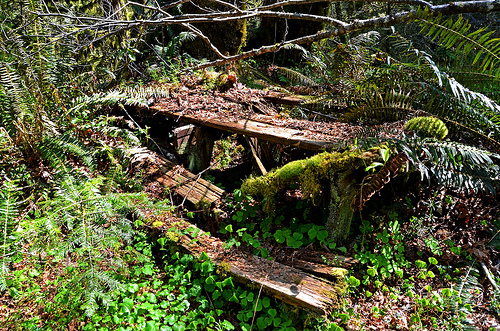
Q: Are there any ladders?
A: No, there are no ladders.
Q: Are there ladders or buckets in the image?
A: No, there are no ladders or buckets.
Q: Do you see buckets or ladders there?
A: No, there are no ladders or buckets.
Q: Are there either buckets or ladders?
A: No, there are no ladders or buckets.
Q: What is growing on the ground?
A: The vine is growing on the ground.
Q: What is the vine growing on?
A: The vine is growing on the ground.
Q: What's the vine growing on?
A: The vine is growing on the ground.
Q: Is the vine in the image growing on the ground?
A: Yes, the vine is growing on the ground.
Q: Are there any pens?
A: No, there are no pens.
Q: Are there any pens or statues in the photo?
A: No, there are no pens or statues.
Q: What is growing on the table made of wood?
A: The moss is growing on the table.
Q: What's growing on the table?
A: The moss is growing on the table.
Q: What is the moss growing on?
A: The moss is growing on the table.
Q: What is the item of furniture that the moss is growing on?
A: The piece of furniture is a table.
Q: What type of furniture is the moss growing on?
A: The moss is growing on the table.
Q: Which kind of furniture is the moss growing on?
A: The moss is growing on the table.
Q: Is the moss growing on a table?
A: Yes, the moss is growing on a table.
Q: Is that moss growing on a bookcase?
A: No, the moss is growing on a table.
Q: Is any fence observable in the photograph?
A: No, there are no fences.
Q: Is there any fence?
A: No, there are no fences.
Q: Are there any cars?
A: No, there are no cars.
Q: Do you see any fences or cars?
A: No, there are no cars or fences.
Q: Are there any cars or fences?
A: No, there are no cars or fences.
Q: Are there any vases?
A: No, there are no vases.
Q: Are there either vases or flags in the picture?
A: No, there are no vases or flags.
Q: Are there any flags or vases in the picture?
A: No, there are no vases or flags.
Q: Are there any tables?
A: Yes, there is a table.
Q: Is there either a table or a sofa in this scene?
A: Yes, there is a table.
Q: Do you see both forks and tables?
A: No, there is a table but no forks.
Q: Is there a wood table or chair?
A: Yes, there is a wood table.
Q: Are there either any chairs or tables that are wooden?
A: Yes, the table is wooden.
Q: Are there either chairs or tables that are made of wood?
A: Yes, the table is made of wood.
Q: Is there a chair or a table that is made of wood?
A: Yes, the table is made of wood.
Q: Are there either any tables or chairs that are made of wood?
A: Yes, the table is made of wood.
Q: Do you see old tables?
A: Yes, there is an old table.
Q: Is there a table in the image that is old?
A: Yes, there is a table that is old.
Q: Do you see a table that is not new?
A: Yes, there is a old table.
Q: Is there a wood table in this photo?
A: Yes, there is a wood table.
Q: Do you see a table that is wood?
A: Yes, there is a wood table.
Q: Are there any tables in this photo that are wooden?
A: Yes, there is a table that is wooden.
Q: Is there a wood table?
A: Yes, there is a table that is made of wood.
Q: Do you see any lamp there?
A: No, there are no lamps.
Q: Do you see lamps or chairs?
A: No, there are no lamps or chairs.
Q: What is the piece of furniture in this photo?
A: The piece of furniture is a table.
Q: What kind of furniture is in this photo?
A: The furniture is a table.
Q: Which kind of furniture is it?
A: The piece of furniture is a table.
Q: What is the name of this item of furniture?
A: This is a table.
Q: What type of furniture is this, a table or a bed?
A: This is a table.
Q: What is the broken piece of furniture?
A: The piece of furniture is a table.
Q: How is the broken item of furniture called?
A: The piece of furniture is a table.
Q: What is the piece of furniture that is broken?
A: The piece of furniture is a table.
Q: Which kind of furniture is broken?
A: The furniture is a table.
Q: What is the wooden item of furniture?
A: The piece of furniture is a table.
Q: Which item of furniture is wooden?
A: The piece of furniture is a table.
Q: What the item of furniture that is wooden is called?
A: The piece of furniture is a table.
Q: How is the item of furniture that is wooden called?
A: The piece of furniture is a table.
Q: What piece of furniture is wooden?
A: The piece of furniture is a table.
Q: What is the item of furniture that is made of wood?
A: The piece of furniture is a table.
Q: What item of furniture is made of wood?
A: The piece of furniture is a table.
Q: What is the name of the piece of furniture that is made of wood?
A: The piece of furniture is a table.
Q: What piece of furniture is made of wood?
A: The piece of furniture is a table.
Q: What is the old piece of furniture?
A: The piece of furniture is a table.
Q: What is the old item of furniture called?
A: The piece of furniture is a table.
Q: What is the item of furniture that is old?
A: The piece of furniture is a table.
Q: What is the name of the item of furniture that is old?
A: The piece of furniture is a table.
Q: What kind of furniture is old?
A: The furniture is a table.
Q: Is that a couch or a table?
A: That is a table.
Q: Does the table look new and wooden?
A: No, the table is wooden but old.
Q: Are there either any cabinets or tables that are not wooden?
A: No, there is a table but it is wooden.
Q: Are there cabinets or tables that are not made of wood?
A: No, there is a table but it is made of wood.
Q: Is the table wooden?
A: Yes, the table is wooden.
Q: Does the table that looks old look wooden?
A: Yes, the table is wooden.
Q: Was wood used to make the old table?
A: Yes, the table is made of wood.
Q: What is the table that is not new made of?
A: The table is made of wood.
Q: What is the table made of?
A: The table is made of wood.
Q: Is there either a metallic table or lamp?
A: No, there is a table but it is wooden.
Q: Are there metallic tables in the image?
A: No, there is a table but it is wooden.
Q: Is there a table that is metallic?
A: No, there is a table but it is wooden.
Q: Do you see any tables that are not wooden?
A: No, there is a table but it is wooden.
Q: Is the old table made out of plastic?
A: No, the table is made of wood.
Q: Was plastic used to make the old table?
A: No, the table is made of wood.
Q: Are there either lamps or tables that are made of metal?
A: No, there is a table but it is made of wood.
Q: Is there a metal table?
A: No, there is a table but it is made of wood.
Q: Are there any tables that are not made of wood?
A: No, there is a table but it is made of wood.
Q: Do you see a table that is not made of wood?
A: No, there is a table but it is made of wood.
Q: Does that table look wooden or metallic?
A: The table is wooden.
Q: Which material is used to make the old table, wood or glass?
A: The table is made of wood.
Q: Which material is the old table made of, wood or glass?
A: The table is made of wood.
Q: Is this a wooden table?
A: Yes, this is a wooden table.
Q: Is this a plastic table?
A: No, this is a wooden table.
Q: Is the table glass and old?
A: No, the table is old but wooden.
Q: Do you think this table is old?
A: Yes, the table is old.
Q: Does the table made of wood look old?
A: Yes, the table is old.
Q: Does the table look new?
A: No, the table is old.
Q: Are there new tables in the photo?
A: No, there is a table but it is old.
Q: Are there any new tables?
A: No, there is a table but it is old.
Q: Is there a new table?
A: No, there is a table but it is old.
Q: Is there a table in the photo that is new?
A: No, there is a table but it is old.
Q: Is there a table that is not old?
A: No, there is a table but it is old.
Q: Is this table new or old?
A: The table is old.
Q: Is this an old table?
A: Yes, this is an old table.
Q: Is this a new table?
A: No, this is an old table.